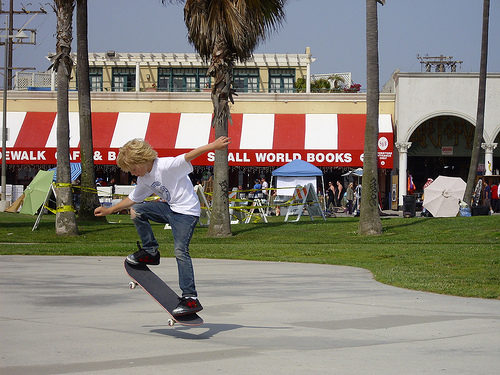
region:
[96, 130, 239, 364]
Young boy skate boarding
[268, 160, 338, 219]
A canopy set up in park for event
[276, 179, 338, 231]
Warning sign for people to be aware of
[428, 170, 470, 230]
An umbrella sitting on the ground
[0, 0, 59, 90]
a utility pole with different gadgets on it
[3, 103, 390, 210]
A covered area to buy goods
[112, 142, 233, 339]
Young boy doing tricks on a skate board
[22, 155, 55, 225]
A green umbrella laying on the ground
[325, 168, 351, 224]
People walking and looking at goods to buy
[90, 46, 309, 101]
Building with lots of windows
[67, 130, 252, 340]
A boy doing a skateboard trick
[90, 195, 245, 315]
Blue jeans that are ripped on one knee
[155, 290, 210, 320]
A black/red sneaker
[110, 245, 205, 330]
A skate board with white/red wheels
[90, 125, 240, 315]
A boy with a white T-shirt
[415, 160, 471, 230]
A white umbrella on the ground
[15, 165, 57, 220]
A green umbrella on the ground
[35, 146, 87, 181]
A blue/white striped umbrella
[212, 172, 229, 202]
Black graffiti on a tree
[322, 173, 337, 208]
A woman in a black shit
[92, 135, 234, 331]
a boy performing a trick on a skateboard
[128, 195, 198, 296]
a boy wearing blue jeans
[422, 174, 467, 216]
a white parasol on the grass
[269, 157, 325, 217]
a blue canopy on the grass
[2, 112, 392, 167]
a red and white stripe canopy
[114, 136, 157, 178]
a boy with blond hair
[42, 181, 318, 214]
yellow security tape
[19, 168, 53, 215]
a green parasol on the grass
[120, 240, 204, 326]
a boy with his feet on a skateboard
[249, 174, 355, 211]
people walking on a sidewalk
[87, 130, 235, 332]
A BOY ON A SKATEBOARD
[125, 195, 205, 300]
A PAIR OF JEANS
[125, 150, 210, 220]
A WHITE TEE SHIRT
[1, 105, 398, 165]
A RED AND WHITE AWNING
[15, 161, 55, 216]
A GREEN UMBRELLA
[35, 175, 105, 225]
YELLOW TAPE AROUND TWO TREES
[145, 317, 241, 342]
A SHADOW ON THE GROUND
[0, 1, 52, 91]
AN ELECTRICAL POLE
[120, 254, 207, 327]
A WOODEN SKATEBOARD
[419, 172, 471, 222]
A WHITE UMBRELLA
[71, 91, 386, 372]
a kid that is skateboarding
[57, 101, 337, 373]
a young kid skateboarding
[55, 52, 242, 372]
a boy that is skateboarding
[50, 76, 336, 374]
a young boy that is skateboarding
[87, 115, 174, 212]
a kid with blonde hair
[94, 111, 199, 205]
a kid with long blonde hair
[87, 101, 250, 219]
a kid wearing a shirt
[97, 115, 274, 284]
a boy wearing a shirt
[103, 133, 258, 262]
a kid wearing a white shirt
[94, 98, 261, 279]
a boy wearing a white shirt